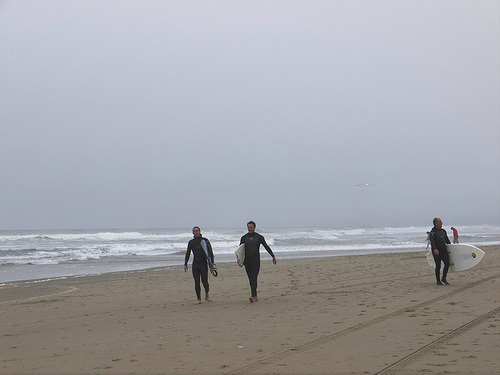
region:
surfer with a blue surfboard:
[181, 225, 223, 308]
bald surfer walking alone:
[424, 214, 452, 287]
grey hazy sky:
[0, 3, 495, 235]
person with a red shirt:
[450, 220, 463, 247]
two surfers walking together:
[184, 220, 279, 307]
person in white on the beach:
[423, 227, 432, 252]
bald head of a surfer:
[431, 216, 446, 230]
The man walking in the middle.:
[237, 219, 277, 304]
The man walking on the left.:
[185, 221, 214, 304]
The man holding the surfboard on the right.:
[427, 214, 486, 289]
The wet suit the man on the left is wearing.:
[186, 237, 213, 298]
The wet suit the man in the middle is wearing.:
[240, 232, 268, 300]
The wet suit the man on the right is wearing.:
[431, 226, 451, 277]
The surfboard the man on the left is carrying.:
[195, 235, 210, 270]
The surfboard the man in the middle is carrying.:
[230, 240, 245, 265]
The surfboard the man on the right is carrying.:
[427, 240, 482, 270]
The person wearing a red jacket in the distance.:
[450, 223, 461, 242]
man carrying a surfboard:
[403, 182, 494, 287]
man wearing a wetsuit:
[225, 200, 291, 305]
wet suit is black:
[228, 203, 288, 318]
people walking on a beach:
[8, 168, 494, 369]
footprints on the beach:
[46, 234, 399, 366]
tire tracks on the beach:
[225, 289, 497, 369]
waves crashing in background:
[45, 182, 437, 276]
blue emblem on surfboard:
[445, 245, 488, 275]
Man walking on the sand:
[179, 216, 221, 319]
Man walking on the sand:
[233, 216, 283, 301]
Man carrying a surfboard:
[176, 216, 215, 303]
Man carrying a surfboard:
[230, 214, 286, 309]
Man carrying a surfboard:
[418, 216, 480, 291]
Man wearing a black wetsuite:
[232, 214, 279, 324]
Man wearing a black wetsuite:
[400, 205, 455, 284]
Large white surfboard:
[414, 237, 494, 278]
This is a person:
[231, 215, 284, 315]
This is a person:
[419, 208, 484, 299]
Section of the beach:
[17, 279, 108, 325]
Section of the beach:
[17, 319, 124, 371]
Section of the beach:
[317, 307, 406, 373]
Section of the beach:
[310, 260, 381, 306]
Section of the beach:
[410, 305, 497, 372]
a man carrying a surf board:
[235, 223, 272, 307]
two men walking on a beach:
[179, 217, 279, 309]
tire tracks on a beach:
[336, 273, 496, 373]